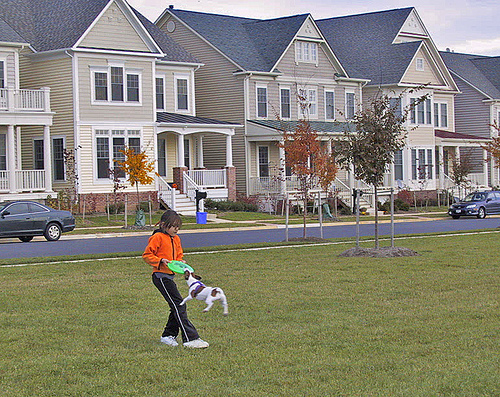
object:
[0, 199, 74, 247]
car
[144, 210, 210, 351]
girl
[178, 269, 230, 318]
dog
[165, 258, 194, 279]
frisbee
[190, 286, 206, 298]
patch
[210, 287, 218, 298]
patch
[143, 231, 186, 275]
jacket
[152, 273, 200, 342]
pants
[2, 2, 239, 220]
house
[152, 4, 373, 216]
house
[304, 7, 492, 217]
house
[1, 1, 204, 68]
roof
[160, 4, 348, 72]
roof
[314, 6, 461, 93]
roof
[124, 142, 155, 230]
tree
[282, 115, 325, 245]
tree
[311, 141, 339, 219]
tree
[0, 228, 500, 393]
park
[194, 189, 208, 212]
mailbox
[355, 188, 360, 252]
support pole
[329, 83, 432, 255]
tree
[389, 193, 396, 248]
support pole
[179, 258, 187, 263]
hand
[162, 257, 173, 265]
hand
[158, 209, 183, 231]
hair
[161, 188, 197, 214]
steps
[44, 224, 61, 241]
rear tire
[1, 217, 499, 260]
road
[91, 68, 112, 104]
window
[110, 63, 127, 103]
window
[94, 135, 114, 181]
window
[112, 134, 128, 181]
window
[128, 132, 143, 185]
window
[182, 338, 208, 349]
sport shoe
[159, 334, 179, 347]
sport shoe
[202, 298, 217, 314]
left hind leg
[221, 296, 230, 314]
right hind leg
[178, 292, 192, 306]
left front leg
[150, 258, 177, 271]
lower torso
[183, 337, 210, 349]
right foot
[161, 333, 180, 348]
left foot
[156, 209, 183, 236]
head